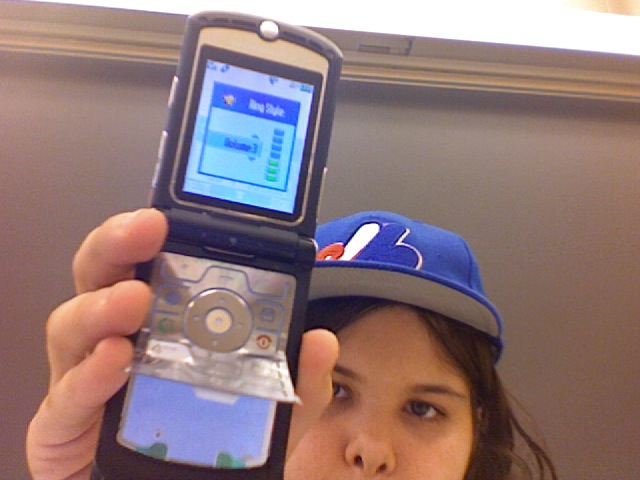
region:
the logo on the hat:
[341, 219, 420, 273]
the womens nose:
[339, 425, 394, 478]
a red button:
[253, 336, 273, 355]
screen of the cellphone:
[194, 53, 295, 208]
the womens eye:
[402, 394, 445, 418]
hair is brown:
[490, 433, 518, 474]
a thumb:
[299, 332, 331, 378]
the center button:
[192, 298, 245, 341]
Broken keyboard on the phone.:
[124, 319, 283, 465]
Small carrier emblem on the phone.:
[256, 6, 281, 42]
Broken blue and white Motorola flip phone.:
[89, 0, 348, 473]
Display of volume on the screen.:
[221, 78, 294, 195]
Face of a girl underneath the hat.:
[285, 262, 570, 477]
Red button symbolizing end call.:
[245, 324, 279, 353]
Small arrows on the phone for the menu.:
[186, 275, 253, 348]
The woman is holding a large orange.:
[303, 411, 321, 438]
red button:
[253, 334, 274, 354]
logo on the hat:
[337, 214, 415, 267]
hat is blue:
[431, 240, 463, 273]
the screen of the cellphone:
[199, 54, 293, 209]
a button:
[156, 314, 174, 333]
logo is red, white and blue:
[331, 225, 412, 266]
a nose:
[345, 428, 398, 473]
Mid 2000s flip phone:
[110, 9, 344, 478]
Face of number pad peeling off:
[112, 245, 311, 474]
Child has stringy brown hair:
[298, 292, 563, 477]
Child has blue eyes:
[311, 375, 455, 438]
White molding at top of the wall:
[7, 0, 631, 117]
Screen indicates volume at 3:
[196, 82, 300, 192]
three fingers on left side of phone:
[16, 190, 175, 475]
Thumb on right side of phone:
[291, 332, 340, 445]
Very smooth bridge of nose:
[343, 385, 411, 470]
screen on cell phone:
[205, 54, 319, 220]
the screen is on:
[171, 29, 320, 221]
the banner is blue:
[221, 82, 306, 126]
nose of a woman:
[347, 409, 396, 475]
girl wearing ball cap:
[297, 196, 518, 342]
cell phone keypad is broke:
[126, 240, 308, 409]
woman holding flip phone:
[104, 6, 340, 475]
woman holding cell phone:
[81, 3, 354, 479]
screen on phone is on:
[165, 41, 322, 223]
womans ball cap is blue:
[289, 201, 514, 365]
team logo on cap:
[314, 210, 406, 268]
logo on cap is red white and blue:
[317, 212, 411, 280]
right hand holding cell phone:
[22, 205, 337, 478]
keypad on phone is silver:
[120, 237, 307, 431]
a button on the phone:
[248, 363, 262, 388]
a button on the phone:
[257, 374, 273, 395]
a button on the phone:
[213, 346, 227, 388]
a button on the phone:
[162, 341, 183, 375]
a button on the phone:
[133, 354, 149, 375]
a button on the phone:
[188, 284, 213, 344]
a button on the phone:
[212, 259, 248, 295]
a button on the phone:
[164, 282, 211, 364]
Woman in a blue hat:
[228, 205, 535, 479]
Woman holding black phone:
[51, 7, 556, 442]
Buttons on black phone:
[130, 270, 301, 390]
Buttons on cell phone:
[122, 271, 303, 397]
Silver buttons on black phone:
[145, 270, 294, 397]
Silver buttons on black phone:
[111, 271, 301, 421]